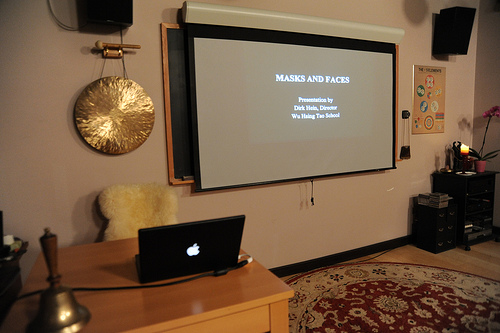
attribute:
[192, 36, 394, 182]
projector screen — large, white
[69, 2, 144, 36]
speaker — black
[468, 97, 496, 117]
flower — pink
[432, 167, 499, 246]
book shelf — small, black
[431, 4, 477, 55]
speaker — black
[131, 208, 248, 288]
laptop — open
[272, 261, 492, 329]
rug — dark red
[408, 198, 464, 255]
filing cabinet — small, black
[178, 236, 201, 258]
apple — white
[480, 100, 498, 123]
flower — large, dark pink